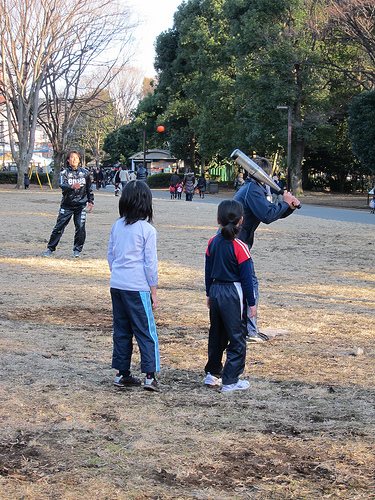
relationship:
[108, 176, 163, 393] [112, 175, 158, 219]
child has hair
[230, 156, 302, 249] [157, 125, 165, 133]
people playing ball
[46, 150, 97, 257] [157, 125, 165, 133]
man playing ball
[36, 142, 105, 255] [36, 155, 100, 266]
man wearing a outfit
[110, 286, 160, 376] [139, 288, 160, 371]
pant with stripe